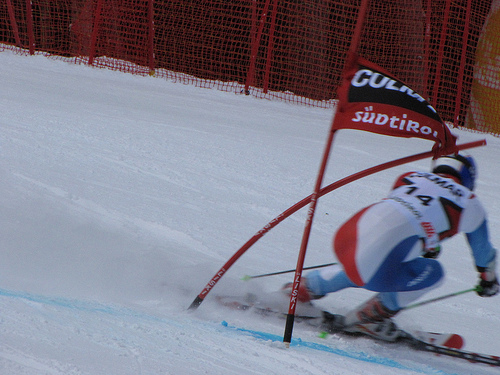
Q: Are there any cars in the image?
A: No, there are no cars.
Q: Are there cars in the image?
A: No, there are no cars.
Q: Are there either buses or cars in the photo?
A: No, there are no cars or buses.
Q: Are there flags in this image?
A: Yes, there is a flag.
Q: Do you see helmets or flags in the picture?
A: Yes, there is a flag.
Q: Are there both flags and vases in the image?
A: No, there is a flag but no vases.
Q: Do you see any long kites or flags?
A: Yes, there is a long flag.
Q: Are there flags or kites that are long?
A: Yes, the flag is long.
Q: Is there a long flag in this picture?
A: Yes, there is a long flag.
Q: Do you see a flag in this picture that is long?
A: Yes, there is a flag that is long.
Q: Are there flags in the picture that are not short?
A: Yes, there is a long flag.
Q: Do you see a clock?
A: No, there are no clocks.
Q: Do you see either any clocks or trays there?
A: No, there are no clocks or trays.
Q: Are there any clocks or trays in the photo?
A: No, there are no clocks or trays.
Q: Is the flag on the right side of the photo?
A: Yes, the flag is on the right of the image.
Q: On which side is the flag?
A: The flag is on the right of the image.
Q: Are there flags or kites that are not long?
A: No, there is a flag but it is long.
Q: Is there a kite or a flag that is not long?
A: No, there is a flag but it is long.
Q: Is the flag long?
A: Yes, the flag is long.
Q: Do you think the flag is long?
A: Yes, the flag is long.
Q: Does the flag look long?
A: Yes, the flag is long.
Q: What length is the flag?
A: The flag is long.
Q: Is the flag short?
A: No, the flag is long.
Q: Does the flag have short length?
A: No, the flag is long.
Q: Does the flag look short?
A: No, the flag is long.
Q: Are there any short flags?
A: No, there is a flag but it is long.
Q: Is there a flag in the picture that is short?
A: No, there is a flag but it is long.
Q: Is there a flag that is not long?
A: No, there is a flag but it is long.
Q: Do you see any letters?
A: Yes, there are letters.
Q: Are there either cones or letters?
A: Yes, there are letters.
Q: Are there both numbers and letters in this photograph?
A: Yes, there are both letters and numbers.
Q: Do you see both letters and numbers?
A: Yes, there are both letters and numbers.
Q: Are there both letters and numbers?
A: Yes, there are both letters and numbers.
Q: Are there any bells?
A: No, there are no bells.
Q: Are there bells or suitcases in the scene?
A: No, there are no bells or suitcases.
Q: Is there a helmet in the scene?
A: Yes, there is a helmet.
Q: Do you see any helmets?
A: Yes, there is a helmet.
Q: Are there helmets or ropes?
A: Yes, there is a helmet.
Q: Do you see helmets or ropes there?
A: Yes, there is a helmet.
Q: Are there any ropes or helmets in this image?
A: Yes, there is a helmet.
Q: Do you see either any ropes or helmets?
A: Yes, there is a helmet.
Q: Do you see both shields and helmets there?
A: No, there is a helmet but no shields.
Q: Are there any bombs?
A: No, there are no bombs.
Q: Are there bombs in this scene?
A: No, there are no bombs.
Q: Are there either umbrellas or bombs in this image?
A: No, there are no bombs or umbrellas.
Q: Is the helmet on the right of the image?
A: Yes, the helmet is on the right of the image.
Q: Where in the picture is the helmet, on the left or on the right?
A: The helmet is on the right of the image.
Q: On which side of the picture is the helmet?
A: The helmet is on the right of the image.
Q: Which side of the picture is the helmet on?
A: The helmet is on the right of the image.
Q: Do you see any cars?
A: No, there are no cars.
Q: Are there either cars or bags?
A: No, there are no cars or bags.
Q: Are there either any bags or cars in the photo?
A: No, there are no cars or bags.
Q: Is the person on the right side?
A: Yes, the person is on the right of the image.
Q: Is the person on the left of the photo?
A: No, the person is on the right of the image.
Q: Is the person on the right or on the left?
A: The person is on the right of the image.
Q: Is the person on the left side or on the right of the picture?
A: The person is on the right of the image.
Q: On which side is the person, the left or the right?
A: The person is on the right of the image.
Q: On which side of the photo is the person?
A: The person is on the right of the image.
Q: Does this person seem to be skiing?
A: Yes, the person is skiing.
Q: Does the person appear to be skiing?
A: Yes, the person is skiing.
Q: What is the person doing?
A: The person is skiing.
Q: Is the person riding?
A: No, the person is skiing.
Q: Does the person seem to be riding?
A: No, the person is skiing.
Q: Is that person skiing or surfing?
A: The person is skiing.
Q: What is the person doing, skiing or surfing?
A: The person is skiing.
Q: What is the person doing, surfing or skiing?
A: The person is skiing.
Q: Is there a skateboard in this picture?
A: No, there are no skateboards.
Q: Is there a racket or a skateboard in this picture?
A: No, there are no skateboards or rackets.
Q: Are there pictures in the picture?
A: No, there are no pictures.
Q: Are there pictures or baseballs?
A: No, there are no pictures or baseballs.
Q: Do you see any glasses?
A: No, there are no glasses.